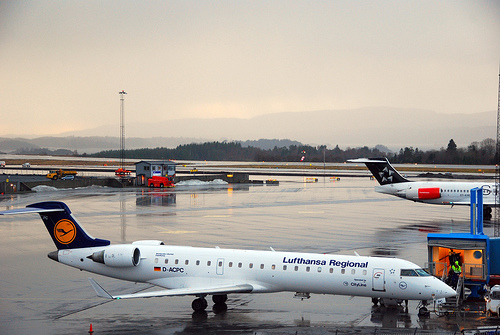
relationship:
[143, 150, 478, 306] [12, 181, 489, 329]
cone on pavement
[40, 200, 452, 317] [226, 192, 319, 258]
plane on ground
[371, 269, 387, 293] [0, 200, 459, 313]
door on plane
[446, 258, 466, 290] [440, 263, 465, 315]
man walking down steps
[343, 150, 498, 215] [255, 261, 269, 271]
plane has window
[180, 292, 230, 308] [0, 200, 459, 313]
tires under plane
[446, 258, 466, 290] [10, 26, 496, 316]
man at airport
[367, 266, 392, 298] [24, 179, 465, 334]
door on plane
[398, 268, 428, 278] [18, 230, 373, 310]
windshield on plane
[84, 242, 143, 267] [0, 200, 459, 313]
engine on plane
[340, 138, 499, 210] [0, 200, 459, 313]
jet on plane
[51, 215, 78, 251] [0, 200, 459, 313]
logo on plane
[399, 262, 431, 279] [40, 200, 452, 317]
window on plane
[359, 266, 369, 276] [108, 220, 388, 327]
window on plane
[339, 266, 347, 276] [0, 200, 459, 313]
window on plane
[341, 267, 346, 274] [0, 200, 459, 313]
window on plane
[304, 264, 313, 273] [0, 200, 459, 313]
window on plane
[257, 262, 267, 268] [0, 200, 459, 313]
window on plane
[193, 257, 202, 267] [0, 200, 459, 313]
window on plane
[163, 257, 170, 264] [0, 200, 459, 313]
window on plane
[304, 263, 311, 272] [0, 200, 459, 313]
window on plane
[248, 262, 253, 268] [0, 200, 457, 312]
window on plane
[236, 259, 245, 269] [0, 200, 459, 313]
window on plane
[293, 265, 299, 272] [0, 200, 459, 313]
small window on plane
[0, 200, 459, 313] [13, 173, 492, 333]
plane at terminal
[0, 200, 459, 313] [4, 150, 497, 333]
plane at airport